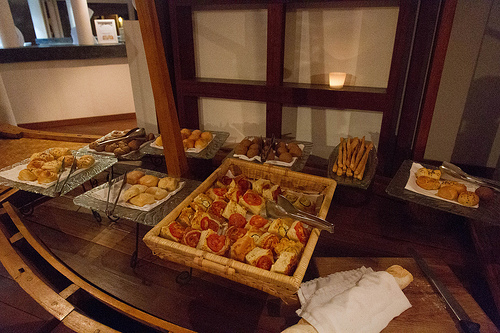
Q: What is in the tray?
A: Cinnamon rolls.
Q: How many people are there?
A: None.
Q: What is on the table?
A: Bread.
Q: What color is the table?
A: Brown.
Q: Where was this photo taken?
A: Inside a building.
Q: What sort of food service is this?
A: Catering.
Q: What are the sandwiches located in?
A: A wooden basket.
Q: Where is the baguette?
A: Under a towel on the right side of the table.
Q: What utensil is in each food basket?
A: Pinchers.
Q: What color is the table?
A: Brown.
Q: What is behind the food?
A: A window with a closed curtain.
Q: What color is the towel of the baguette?
A: White.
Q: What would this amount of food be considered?
A: A buffet.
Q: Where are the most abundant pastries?
A: Wicker basket.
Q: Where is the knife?
A: On cutting board.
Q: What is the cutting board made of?
A: Wood.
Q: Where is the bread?
A: Below towel.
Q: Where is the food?
A: On the table.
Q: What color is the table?
A: Brown.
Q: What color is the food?
A: Brown and red.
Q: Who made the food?
A: A cook/chef.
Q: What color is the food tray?
A: Brown.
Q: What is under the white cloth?
A: Bread.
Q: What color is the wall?
A: White.